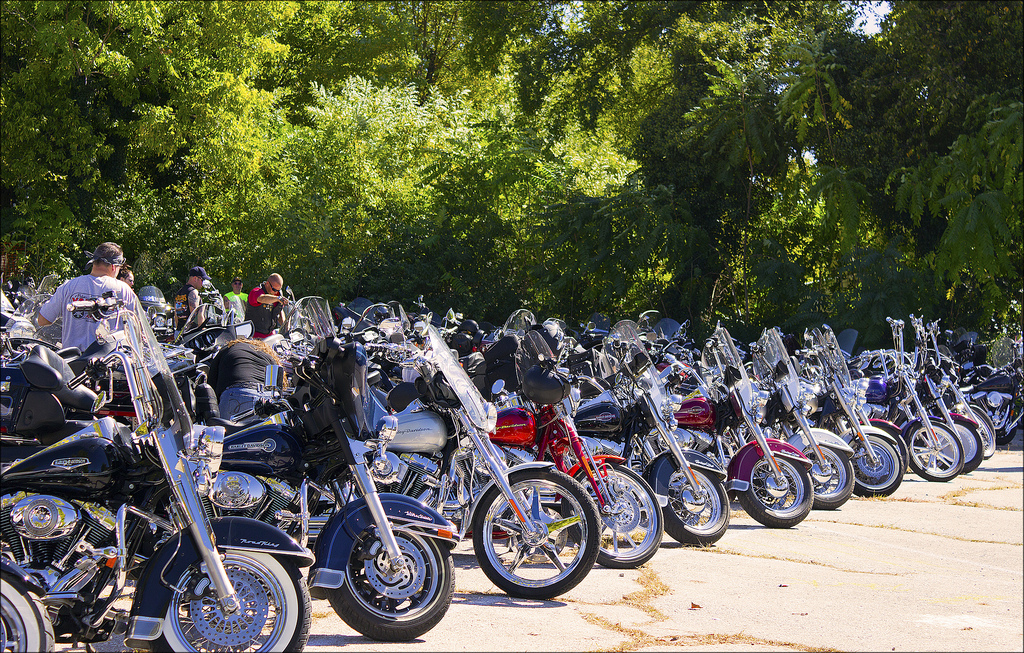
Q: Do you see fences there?
A: No, there are no fences.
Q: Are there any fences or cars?
A: No, there are no fences or cars.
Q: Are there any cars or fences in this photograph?
A: No, there are no fences or cars.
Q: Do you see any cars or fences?
A: No, there are no fences or cars.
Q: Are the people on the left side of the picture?
A: Yes, the people are on the left of the image.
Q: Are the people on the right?
A: No, the people are on the left of the image.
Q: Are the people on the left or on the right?
A: The people are on the left of the image.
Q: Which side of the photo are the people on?
A: The people are on the left of the image.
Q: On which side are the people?
A: The people are on the left of the image.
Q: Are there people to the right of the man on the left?
A: Yes, there are people to the right of the man.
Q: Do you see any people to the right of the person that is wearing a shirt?
A: Yes, there are people to the right of the man.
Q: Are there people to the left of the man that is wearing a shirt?
A: No, the people are to the right of the man.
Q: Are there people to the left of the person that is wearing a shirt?
A: No, the people are to the right of the man.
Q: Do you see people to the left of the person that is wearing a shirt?
A: No, the people are to the right of the man.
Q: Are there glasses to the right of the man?
A: No, there are people to the right of the man.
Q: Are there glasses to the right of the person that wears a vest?
A: No, there are people to the right of the man.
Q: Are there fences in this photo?
A: No, there are no fences.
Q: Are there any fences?
A: No, there are no fences.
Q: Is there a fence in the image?
A: No, there are no fences.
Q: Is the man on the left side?
A: Yes, the man is on the left of the image.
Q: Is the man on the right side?
A: No, the man is on the left of the image.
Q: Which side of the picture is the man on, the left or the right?
A: The man is on the left of the image.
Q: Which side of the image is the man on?
A: The man is on the left of the image.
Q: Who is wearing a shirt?
A: The man is wearing a shirt.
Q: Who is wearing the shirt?
A: The man is wearing a shirt.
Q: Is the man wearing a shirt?
A: Yes, the man is wearing a shirt.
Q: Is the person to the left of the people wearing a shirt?
A: Yes, the man is wearing a shirt.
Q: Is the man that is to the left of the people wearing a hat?
A: No, the man is wearing a shirt.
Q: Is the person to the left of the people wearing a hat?
A: No, the man is wearing a shirt.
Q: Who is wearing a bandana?
A: The man is wearing a bandana.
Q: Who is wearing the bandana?
A: The man is wearing a bandana.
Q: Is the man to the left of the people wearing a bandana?
A: Yes, the man is wearing a bandana.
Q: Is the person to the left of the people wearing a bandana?
A: Yes, the man is wearing a bandana.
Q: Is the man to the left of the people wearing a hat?
A: No, the man is wearing a bandana.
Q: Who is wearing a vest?
A: The man is wearing a vest.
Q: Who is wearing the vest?
A: The man is wearing a vest.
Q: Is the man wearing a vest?
A: Yes, the man is wearing a vest.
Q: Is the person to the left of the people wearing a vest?
A: Yes, the man is wearing a vest.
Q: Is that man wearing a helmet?
A: No, the man is wearing a vest.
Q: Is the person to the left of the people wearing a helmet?
A: No, the man is wearing a vest.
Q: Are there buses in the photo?
A: No, there are no buses.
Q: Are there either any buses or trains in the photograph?
A: No, there are no buses or trains.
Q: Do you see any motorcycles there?
A: Yes, there is a motorcycle.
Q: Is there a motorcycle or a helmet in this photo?
A: Yes, there is a motorcycle.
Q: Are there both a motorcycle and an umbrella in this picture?
A: No, there is a motorcycle but no umbrellas.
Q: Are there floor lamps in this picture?
A: No, there are no floor lamps.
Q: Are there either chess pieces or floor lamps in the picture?
A: No, there are no floor lamps or chess pieces.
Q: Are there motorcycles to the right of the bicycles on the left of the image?
A: Yes, there is a motorcycle to the right of the bicycles.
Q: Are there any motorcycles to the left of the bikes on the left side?
A: No, the motorcycle is to the right of the bicycles.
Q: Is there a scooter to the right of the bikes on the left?
A: No, there is a motorcycle to the right of the bikes.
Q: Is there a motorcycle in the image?
A: Yes, there are motorcycles.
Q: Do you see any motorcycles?
A: Yes, there are motorcycles.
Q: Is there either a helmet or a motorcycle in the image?
A: Yes, there are motorcycles.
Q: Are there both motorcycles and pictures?
A: No, there are motorcycles but no pictures.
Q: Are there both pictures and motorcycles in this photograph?
A: No, there are motorcycles but no pictures.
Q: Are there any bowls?
A: No, there are no bowls.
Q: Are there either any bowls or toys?
A: No, there are no bowls or toys.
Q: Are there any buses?
A: No, there are no buses.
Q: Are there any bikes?
A: Yes, there is a bike.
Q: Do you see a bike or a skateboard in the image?
A: Yes, there is a bike.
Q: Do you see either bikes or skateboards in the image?
A: Yes, there is a bike.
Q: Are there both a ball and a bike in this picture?
A: No, there is a bike but no balls.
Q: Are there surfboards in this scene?
A: No, there are no surfboards.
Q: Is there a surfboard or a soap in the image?
A: No, there are no surfboards or soaps.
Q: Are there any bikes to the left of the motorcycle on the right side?
A: Yes, there is a bike to the left of the motorcycle.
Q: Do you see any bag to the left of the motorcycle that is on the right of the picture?
A: No, there is a bike to the left of the motorbike.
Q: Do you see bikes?
A: Yes, there are bikes.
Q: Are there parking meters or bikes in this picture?
A: Yes, there are bikes.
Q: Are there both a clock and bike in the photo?
A: No, there are bikes but no clocks.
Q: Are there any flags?
A: No, there are no flags.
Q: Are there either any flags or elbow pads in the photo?
A: No, there are no flags or elbow pads.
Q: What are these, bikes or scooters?
A: These are bikes.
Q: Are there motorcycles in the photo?
A: Yes, there is a motorcycle.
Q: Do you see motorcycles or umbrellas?
A: Yes, there is a motorcycle.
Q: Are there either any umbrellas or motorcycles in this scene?
A: Yes, there is a motorcycle.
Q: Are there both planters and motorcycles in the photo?
A: No, there is a motorcycle but no planters.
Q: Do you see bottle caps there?
A: No, there are no bottle caps.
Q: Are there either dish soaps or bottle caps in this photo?
A: No, there are no bottle caps or dish soaps.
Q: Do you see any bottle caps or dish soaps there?
A: No, there are no bottle caps or dish soaps.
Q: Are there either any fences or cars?
A: No, there are no cars or fences.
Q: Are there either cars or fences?
A: No, there are no cars or fences.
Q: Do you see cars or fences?
A: No, there are no cars or fences.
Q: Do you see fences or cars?
A: No, there are no cars or fences.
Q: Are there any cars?
A: No, there are no cars.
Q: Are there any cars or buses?
A: No, there are no cars or buses.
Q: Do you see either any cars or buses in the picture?
A: No, there are no cars or buses.